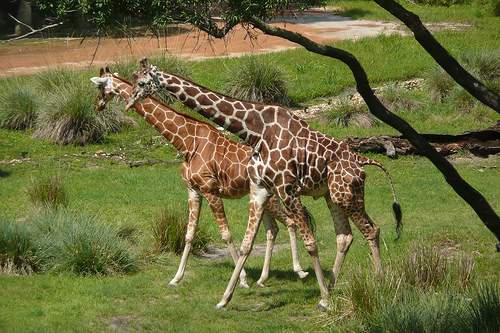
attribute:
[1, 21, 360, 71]
pond — muddy, brown, unclean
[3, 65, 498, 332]
grass — green, splotchy, multi-lengthed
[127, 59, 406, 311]
giraffe — walking, spotted, brown, bent, two-toned, tall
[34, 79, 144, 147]
bush — green, clumpy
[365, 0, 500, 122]
limb — long, leaning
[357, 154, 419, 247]
tail — wispy, long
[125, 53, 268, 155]
neck — long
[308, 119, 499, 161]
trunk — fallen, wood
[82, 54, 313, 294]
giraffe — walking, bent, two-toned, tall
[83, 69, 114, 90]
ear — white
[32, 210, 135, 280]
bush — green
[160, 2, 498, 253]
limb — leaning, leafy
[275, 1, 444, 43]
ground — bare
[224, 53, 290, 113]
bush — green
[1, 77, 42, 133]
bush — green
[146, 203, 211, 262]
bush — green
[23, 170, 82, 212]
bush — green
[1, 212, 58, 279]
bush — green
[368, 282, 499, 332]
bush — green